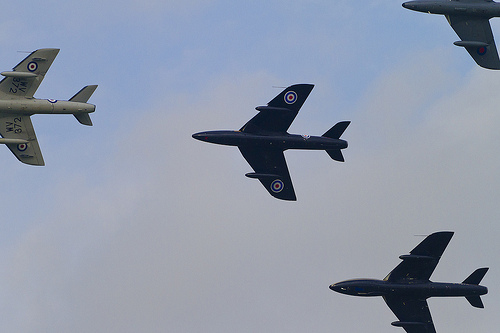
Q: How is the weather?
A: It is cloudy.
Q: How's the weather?
A: It is cloudy.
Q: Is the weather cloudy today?
A: Yes, it is cloudy.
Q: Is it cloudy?
A: Yes, it is cloudy.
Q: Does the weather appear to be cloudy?
A: Yes, it is cloudy.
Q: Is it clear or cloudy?
A: It is cloudy.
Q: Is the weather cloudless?
A: No, it is cloudy.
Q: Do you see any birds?
A: No, there are no birds.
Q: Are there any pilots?
A: No, there are no pilots.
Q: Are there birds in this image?
A: No, there are no birds.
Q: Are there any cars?
A: No, there are no cars.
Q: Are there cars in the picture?
A: No, there are no cars.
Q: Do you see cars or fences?
A: No, there are no cars or fences.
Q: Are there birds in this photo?
A: No, there are no birds.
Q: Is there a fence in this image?
A: No, there are no fences.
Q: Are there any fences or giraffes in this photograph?
A: No, there are no fences or giraffes.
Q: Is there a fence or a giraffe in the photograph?
A: No, there are no fences or giraffes.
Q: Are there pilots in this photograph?
A: No, there are no pilots.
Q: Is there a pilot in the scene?
A: No, there are no pilots.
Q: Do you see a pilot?
A: No, there are no pilots.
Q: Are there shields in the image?
A: No, there are no shields.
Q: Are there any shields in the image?
A: No, there are no shields.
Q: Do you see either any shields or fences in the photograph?
A: No, there are no shields or fences.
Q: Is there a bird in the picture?
A: No, there are no birds.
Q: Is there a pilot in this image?
A: No, there are no pilots.